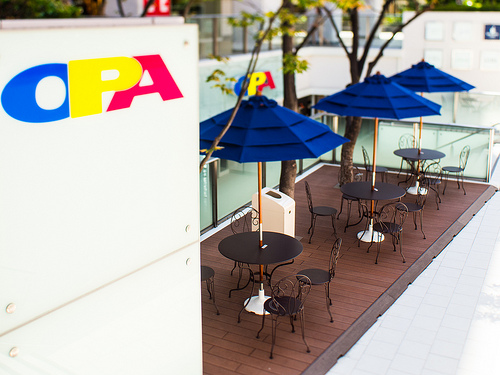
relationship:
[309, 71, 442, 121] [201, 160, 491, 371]
parasol in deck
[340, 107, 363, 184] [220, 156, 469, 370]
tree in deck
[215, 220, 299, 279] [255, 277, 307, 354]
table in chair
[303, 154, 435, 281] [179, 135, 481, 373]
patio table in patio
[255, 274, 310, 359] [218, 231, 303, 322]
chair next to table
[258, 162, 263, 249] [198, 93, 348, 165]
pole under parasol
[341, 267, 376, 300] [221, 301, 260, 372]
red wood on floor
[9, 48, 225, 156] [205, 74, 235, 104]
logo on white